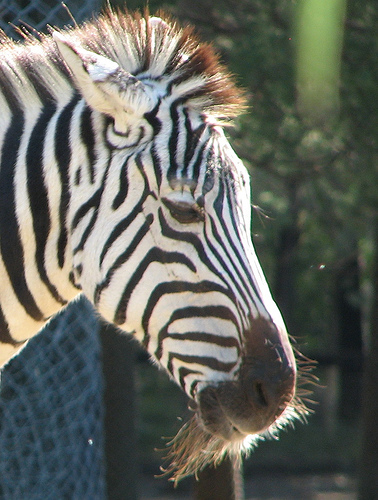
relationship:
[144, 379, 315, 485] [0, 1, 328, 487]
hair on zebra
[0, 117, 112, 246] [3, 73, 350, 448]
stripes on animal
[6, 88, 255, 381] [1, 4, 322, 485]
stripes on animal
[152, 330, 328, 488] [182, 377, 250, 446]
hairs on chin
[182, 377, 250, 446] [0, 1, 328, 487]
chin on zebra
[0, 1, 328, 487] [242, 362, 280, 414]
zebra has nostrils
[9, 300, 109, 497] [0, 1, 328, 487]
fence behind zebra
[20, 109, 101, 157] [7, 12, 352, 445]
stripes on zebra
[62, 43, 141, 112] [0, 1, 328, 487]
ear of zebra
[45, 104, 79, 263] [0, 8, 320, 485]
stripe of fur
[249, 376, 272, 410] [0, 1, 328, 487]
nostril of zebra